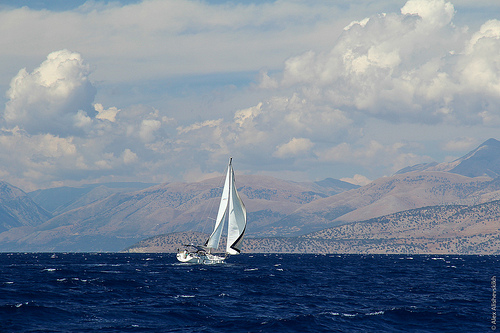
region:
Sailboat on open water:
[179, 154, 250, 259]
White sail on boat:
[210, 155, 245, 253]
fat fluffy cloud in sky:
[9, 50, 96, 134]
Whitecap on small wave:
[324, 308, 390, 319]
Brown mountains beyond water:
[2, 138, 499, 250]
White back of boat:
[175, 248, 194, 263]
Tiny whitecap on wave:
[15, 299, 29, 306]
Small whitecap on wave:
[173, 292, 198, 300]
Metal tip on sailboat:
[230, 157, 235, 170]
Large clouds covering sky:
[3, 3, 498, 185]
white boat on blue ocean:
[167, 143, 245, 270]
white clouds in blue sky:
[6, 18, 61, 68]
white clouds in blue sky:
[3, 76, 74, 140]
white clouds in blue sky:
[12, 136, 77, 203]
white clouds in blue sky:
[70, 181, 147, 246]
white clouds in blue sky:
[103, 53, 173, 130]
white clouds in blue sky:
[177, 51, 261, 131]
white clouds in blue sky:
[259, 31, 356, 106]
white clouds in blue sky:
[307, 111, 344, 161]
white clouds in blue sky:
[336, 68, 398, 133]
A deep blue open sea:
[3, 252, 499, 332]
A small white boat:
[174, 250, 229, 264]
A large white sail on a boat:
[206, 155, 248, 256]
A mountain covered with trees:
[125, 201, 497, 255]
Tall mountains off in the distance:
[0, 162, 437, 235]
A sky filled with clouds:
[4, 2, 498, 166]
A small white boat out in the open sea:
[5, 165, 495, 330]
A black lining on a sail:
[226, 225, 246, 251]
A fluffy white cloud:
[1, 49, 115, 128]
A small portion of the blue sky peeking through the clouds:
[1, 0, 85, 17]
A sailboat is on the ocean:
[10, 27, 480, 322]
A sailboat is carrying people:
[11, 43, 481, 318]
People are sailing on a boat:
[31, 55, 466, 310]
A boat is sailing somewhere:
[16, 32, 477, 313]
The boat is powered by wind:
[11, 41, 459, 323]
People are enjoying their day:
[11, 47, 463, 317]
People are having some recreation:
[15, 25, 466, 320]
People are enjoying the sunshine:
[17, 32, 473, 315]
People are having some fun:
[25, 18, 465, 301]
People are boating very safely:
[17, 24, 471, 317]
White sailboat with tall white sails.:
[174, 158, 246, 265]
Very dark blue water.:
[1, 252, 498, 332]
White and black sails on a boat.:
[206, 157, 249, 256]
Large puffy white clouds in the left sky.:
[0, 50, 127, 182]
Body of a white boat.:
[174, 252, 223, 262]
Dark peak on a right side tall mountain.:
[453, 133, 499, 177]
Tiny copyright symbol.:
[489, 322, 496, 330]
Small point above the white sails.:
[228, 156, 234, 167]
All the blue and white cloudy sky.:
[0, 3, 497, 179]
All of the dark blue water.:
[1, 252, 499, 329]